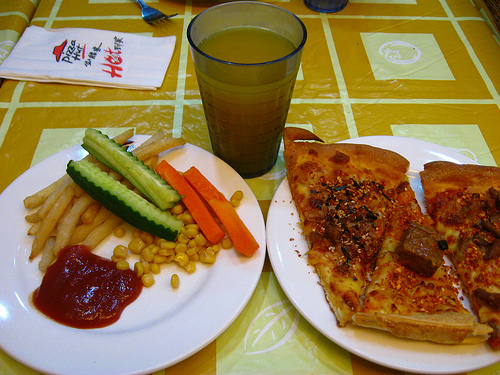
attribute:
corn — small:
[170, 275, 182, 289]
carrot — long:
[178, 160, 265, 259]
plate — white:
[0, 132, 266, 374]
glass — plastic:
[187, 0, 307, 178]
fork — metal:
[135, 8, 182, 30]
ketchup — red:
[31, 243, 141, 325]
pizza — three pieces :
[420, 160, 496, 349]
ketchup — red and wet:
[22, 241, 149, 331]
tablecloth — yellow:
[290, 47, 495, 172]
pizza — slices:
[292, 119, 476, 371]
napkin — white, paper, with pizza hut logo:
[2, 29, 174, 88]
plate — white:
[102, 289, 219, 375]